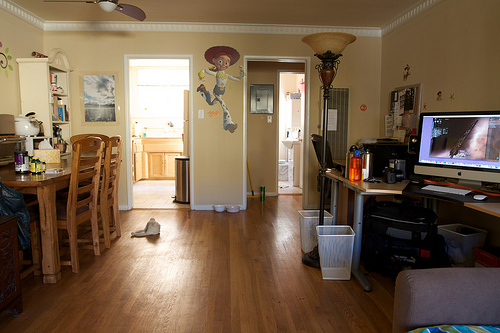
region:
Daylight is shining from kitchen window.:
[126, 56, 189, 208]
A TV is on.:
[416, 112, 499, 170]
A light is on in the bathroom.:
[277, 74, 307, 196]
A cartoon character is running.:
[194, 42, 241, 133]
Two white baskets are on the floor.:
[297, 204, 356, 283]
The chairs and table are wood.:
[0, 135, 121, 282]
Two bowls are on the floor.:
[208, 201, 249, 216]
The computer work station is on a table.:
[326, 108, 497, 267]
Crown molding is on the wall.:
[0, 2, 442, 37]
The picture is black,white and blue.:
[83, 70, 113, 121]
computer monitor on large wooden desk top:
[412, 108, 499, 182]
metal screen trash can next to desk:
[313, 223, 359, 281]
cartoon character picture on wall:
[196, 43, 244, 133]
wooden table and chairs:
[0, 133, 121, 283]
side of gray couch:
[388, 265, 496, 332]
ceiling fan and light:
[85, 0, 145, 22]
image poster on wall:
[81, 71, 119, 123]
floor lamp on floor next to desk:
[301, 30, 356, 270]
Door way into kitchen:
[123, 53, 192, 210]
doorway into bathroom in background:
[277, 69, 306, 193]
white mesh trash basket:
[311, 218, 359, 285]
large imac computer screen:
[410, 104, 497, 194]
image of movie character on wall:
[187, 41, 245, 138]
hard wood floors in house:
[3, 188, 396, 331]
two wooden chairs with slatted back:
[55, 131, 130, 273]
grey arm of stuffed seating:
[387, 256, 498, 332]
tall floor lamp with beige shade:
[292, 27, 364, 273]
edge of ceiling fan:
[52, 1, 151, 23]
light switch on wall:
[193, 105, 208, 127]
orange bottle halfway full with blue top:
[346, 146, 366, 183]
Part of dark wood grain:
[53, 300, 70, 321]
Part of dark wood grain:
[70, 302, 125, 324]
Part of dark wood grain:
[168, 297, 255, 330]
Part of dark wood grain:
[283, 286, 351, 330]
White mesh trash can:
[309, 221, 386, 288]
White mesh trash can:
[293, 204, 350, 266]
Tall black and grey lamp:
[298, 29, 351, 279]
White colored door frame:
[240, 48, 335, 208]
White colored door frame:
[110, 48, 219, 230]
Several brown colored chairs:
[58, 126, 122, 285]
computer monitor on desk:
[411, 104, 498, 184]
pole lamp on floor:
[299, 26, 358, 266]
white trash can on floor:
[313, 220, 358, 286]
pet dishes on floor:
[213, 200, 246, 215]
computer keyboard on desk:
[423, 182, 471, 202]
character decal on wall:
[191, 40, 248, 132]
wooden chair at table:
[61, 130, 106, 277]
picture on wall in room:
[81, 69, 118, 126]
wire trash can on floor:
[312, 221, 354, 283]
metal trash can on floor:
[169, 150, 191, 202]